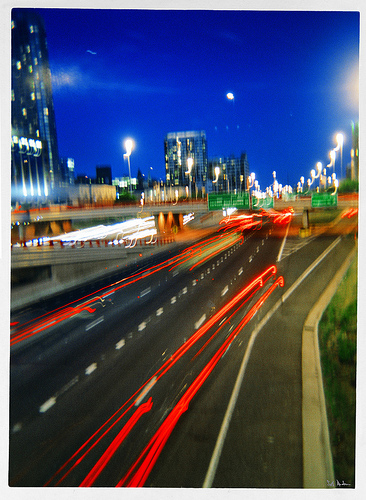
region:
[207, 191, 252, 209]
a sign on a bridge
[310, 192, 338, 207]
a sign on a bridge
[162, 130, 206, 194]
a highrise building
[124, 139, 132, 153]
a light in the distance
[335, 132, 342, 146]
a light in the distance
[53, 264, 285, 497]
streaks of breaklights over time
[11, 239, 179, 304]
ramp on a highway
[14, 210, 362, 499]
a section of a highway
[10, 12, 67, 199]
a tall windowed building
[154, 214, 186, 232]
pillars under a bridge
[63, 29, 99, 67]
white clouds in blue sky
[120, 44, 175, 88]
white clouds in blue sky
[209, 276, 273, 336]
red lights from car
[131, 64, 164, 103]
white clouds in blue sky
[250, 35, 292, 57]
white clouds in blue sky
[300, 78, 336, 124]
white clouds in blue sky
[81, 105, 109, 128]
white clouds in blue sky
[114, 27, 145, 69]
white clouds in blue sky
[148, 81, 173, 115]
white clouds in blue sky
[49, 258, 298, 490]
Bright Red Neon Streaks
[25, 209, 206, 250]
Bright White Neon Lights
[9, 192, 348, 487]
Cars moving at a very fast speed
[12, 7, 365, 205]
Downtown part of the city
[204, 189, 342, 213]
Green and white highway signs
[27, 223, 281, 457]
White Dashed Lines Going Down The Road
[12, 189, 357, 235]
Bridge over the highway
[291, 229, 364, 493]
Curved concete curb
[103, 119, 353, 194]
Rows of blurred street lights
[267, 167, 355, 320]
Offramp part of the highway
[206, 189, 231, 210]
a white and green street sign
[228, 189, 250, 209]
a white and green street sign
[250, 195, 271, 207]
a white and green street sign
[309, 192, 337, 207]
a white and green street sign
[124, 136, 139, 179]
a bright white light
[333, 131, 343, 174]
a bright white light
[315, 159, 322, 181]
a bright white light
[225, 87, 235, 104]
a bright white light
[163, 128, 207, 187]
a very tall grey building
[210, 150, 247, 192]
a very tall grey building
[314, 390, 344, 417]
part of a lawn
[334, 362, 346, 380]
edge of a lawn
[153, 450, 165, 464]
part of a light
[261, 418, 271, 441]
edge of a road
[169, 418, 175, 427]
part of a light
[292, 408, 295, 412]
edge of a road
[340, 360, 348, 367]
part of a grass